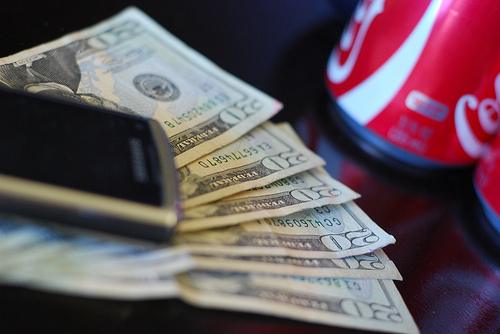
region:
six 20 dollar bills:
[186, 81, 393, 330]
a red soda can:
[323, 8, 489, 174]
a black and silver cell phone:
[1, 83, 181, 240]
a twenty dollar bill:
[1, 14, 283, 170]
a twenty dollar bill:
[167, 120, 324, 207]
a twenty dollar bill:
[180, 167, 362, 232]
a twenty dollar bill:
[96, 202, 396, 260]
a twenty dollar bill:
[106, 250, 403, 280]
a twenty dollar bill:
[40, 278, 420, 332]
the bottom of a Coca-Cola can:
[477, 127, 499, 219]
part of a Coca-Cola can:
[323, 0, 498, 172]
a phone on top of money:
[0, 84, 181, 241]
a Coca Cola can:
[318, 6, 477, 172]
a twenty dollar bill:
[45, 8, 284, 91]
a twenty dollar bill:
[251, 128, 326, 180]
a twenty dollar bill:
[285, 175, 358, 209]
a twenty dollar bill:
[233, 218, 398, 260]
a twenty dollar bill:
[270, 254, 400, 281]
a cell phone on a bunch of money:
[37, 66, 247, 275]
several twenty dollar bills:
[182, 40, 415, 331]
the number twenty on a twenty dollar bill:
[217, 90, 269, 130]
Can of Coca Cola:
[319, 4, 496, 163]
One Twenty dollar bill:
[7, 20, 267, 103]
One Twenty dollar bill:
[170, 116, 316, 181]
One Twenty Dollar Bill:
[176, 160, 312, 220]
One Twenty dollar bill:
[130, 200, 345, 250]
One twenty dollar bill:
[90, 245, 367, 270]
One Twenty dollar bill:
[46, 275, 381, 301]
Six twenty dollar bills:
[1, 20, 411, 330]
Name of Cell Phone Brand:
[118, 117, 155, 191]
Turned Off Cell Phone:
[3, 83, 188, 236]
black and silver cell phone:
[0, 87, 184, 241]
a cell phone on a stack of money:
[5, 3, 422, 332]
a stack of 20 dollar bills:
[3, 11, 415, 332]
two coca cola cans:
[326, 1, 498, 223]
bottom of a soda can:
[323, 98, 464, 190]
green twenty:
[292, 175, 338, 209]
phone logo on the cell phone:
[129, 138, 149, 184]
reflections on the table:
[287, 40, 488, 332]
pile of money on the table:
[2, 10, 414, 332]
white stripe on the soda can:
[343, 2, 456, 123]